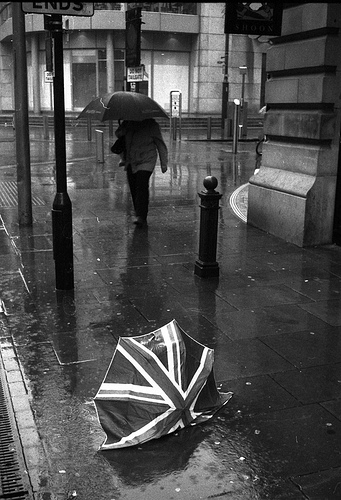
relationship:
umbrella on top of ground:
[84, 324, 236, 446] [46, 221, 181, 297]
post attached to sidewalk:
[189, 169, 228, 284] [146, 241, 191, 289]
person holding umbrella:
[109, 92, 168, 230] [76, 89, 174, 122]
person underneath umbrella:
[109, 92, 168, 230] [87, 93, 175, 122]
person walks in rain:
[76, 92, 168, 228] [36, 385, 89, 456]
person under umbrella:
[76, 92, 168, 228] [74, 90, 170, 138]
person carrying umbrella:
[76, 92, 168, 228] [76, 91, 168, 126]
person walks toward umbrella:
[76, 92, 168, 228] [92, 316, 233, 452]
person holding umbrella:
[109, 92, 168, 230] [76, 91, 168, 126]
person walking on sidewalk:
[109, 92, 168, 230] [0, 125, 338, 497]